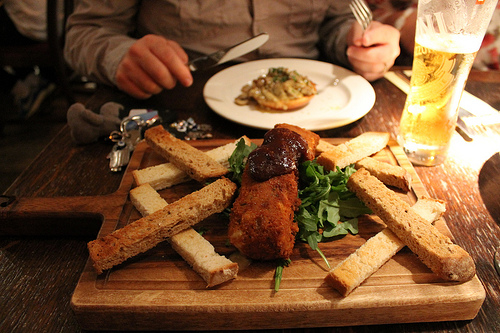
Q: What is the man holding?
A: A knife and fork.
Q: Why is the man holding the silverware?
A: He is getting ready to eat the food.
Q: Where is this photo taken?
A: At a table.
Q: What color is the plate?
A: White.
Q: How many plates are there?
A: One.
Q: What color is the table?
A: Brown.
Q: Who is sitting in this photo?
A: A man.